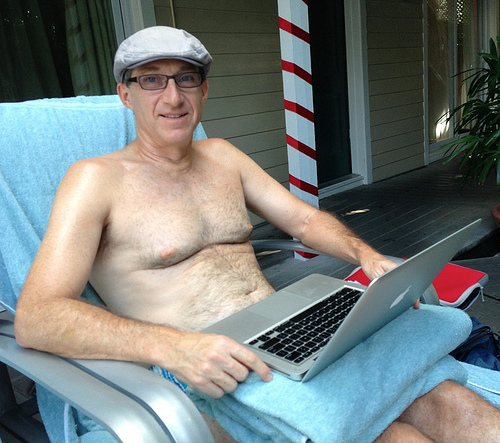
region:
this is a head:
[122, 97, 182, 159]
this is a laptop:
[202, 268, 374, 396]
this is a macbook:
[266, 314, 328, 379]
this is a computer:
[258, 278, 351, 401]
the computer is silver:
[258, 281, 318, 366]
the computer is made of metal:
[302, 330, 344, 425]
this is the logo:
[355, 261, 403, 330]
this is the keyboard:
[302, 314, 329, 358]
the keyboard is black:
[262, 351, 297, 402]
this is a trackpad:
[257, 294, 283, 314]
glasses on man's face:
[125, 70, 206, 90]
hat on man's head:
[98, 23, 215, 82]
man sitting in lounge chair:
[10, 16, 496, 439]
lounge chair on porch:
[1, 90, 499, 441]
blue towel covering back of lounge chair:
[0, 86, 213, 441]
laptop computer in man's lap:
[190, 209, 486, 383]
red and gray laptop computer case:
[341, 240, 493, 312]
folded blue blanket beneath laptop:
[186, 296, 477, 441]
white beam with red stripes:
[278, 0, 321, 261]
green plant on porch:
[431, 35, 499, 180]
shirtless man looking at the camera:
[16, 24, 419, 401]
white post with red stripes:
[278, 0, 323, 188]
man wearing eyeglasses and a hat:
[113, 25, 209, 146]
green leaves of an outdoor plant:
[438, 34, 499, 186]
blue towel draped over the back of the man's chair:
[0, 91, 124, 206]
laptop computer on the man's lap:
[196, 215, 484, 381]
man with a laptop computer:
[10, 25, 495, 442]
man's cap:
[113, 25, 215, 77]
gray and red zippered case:
[346, 240, 491, 308]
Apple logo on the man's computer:
[390, 280, 414, 312]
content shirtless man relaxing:
[1, 20, 498, 440]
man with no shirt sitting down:
[1, 16, 498, 441]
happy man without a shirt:
[11, 20, 499, 441]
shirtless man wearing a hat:
[11, 21, 497, 441]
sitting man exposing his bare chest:
[5, 23, 498, 442]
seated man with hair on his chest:
[10, 22, 499, 441]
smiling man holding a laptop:
[13, 22, 498, 442]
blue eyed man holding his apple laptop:
[13, 25, 485, 440]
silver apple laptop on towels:
[195, 217, 484, 441]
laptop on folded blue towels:
[183, 216, 487, 441]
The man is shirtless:
[18, 23, 393, 363]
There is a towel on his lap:
[192, 317, 482, 441]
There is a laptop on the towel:
[227, 207, 483, 384]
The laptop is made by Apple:
[387, 275, 418, 318]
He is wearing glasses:
[122, 68, 221, 92]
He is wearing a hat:
[93, 15, 243, 76]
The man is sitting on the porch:
[16, 25, 464, 441]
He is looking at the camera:
[108, 30, 229, 162]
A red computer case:
[357, 238, 489, 311]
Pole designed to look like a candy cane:
[273, 3, 332, 255]